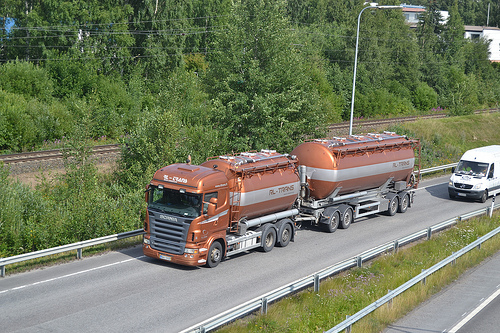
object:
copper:
[201, 169, 223, 184]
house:
[364, 0, 499, 70]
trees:
[1, 0, 497, 145]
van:
[447, 144, 499, 204]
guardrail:
[2, 228, 142, 277]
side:
[0, 166, 148, 251]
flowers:
[310, 288, 334, 306]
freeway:
[1, 162, 499, 333]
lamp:
[348, 3, 402, 136]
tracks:
[1, 105, 499, 170]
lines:
[4, 16, 492, 60]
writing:
[267, 181, 297, 196]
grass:
[207, 210, 499, 332]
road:
[0, 163, 499, 332]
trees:
[0, 0, 333, 260]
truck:
[144, 130, 425, 268]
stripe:
[228, 156, 413, 207]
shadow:
[114, 208, 202, 271]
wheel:
[261, 225, 276, 253]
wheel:
[278, 220, 291, 247]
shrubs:
[1, 100, 93, 146]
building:
[365, 6, 498, 68]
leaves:
[262, 66, 318, 124]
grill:
[146, 210, 191, 256]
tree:
[439, 10, 470, 70]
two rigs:
[203, 130, 423, 252]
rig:
[287, 130, 419, 233]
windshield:
[453, 160, 490, 179]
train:
[3, 143, 122, 166]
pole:
[349, 7, 367, 138]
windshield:
[146, 184, 202, 221]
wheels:
[321, 212, 339, 234]